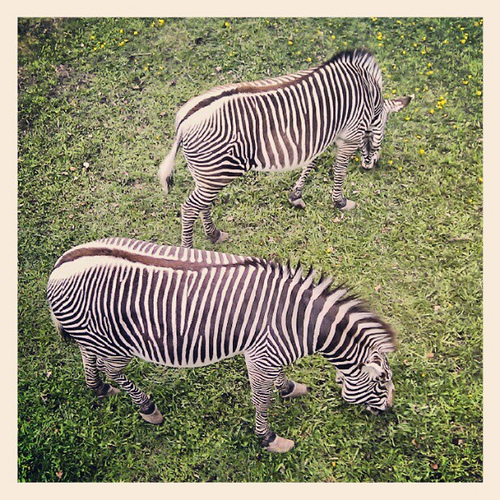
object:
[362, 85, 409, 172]
head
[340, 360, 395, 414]
head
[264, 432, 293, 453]
hooves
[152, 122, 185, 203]
tail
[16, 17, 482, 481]
field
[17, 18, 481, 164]
flower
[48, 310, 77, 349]
tail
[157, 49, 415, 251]
zebra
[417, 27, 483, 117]
fanny pack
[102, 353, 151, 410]
leg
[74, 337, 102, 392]
leg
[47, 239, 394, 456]
zebra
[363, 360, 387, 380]
ear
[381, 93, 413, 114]
ear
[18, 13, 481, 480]
grass field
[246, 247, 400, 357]
mane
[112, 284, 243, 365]
belly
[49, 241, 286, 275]
stripe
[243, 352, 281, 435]
leg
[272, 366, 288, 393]
leg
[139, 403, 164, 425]
hoof